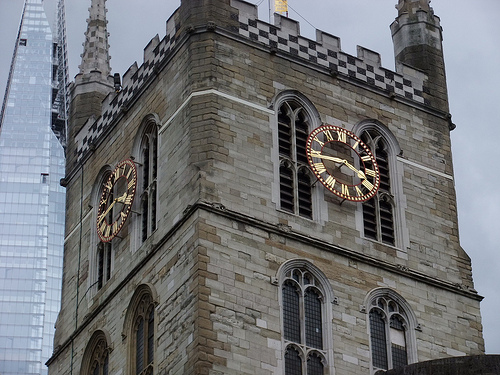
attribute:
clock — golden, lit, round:
[76, 120, 411, 243]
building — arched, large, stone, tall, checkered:
[42, 2, 496, 369]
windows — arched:
[82, 120, 418, 365]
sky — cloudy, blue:
[1, 4, 499, 334]